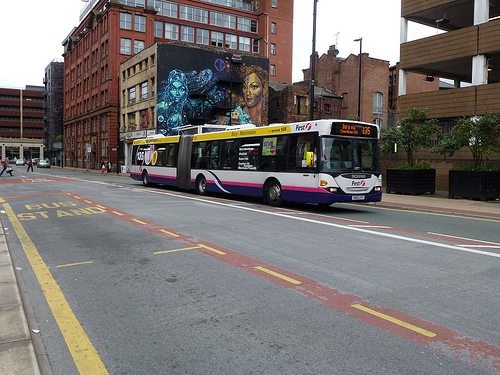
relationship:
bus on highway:
[129, 118, 382, 208] [1, 161, 499, 374]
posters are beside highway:
[156, 41, 269, 133] [1, 161, 499, 374]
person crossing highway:
[26, 157, 34, 172] [1, 161, 499, 374]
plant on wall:
[381, 108, 443, 170] [380, 155, 499, 199]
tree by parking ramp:
[430, 112, 499, 171] [398, 0, 499, 159]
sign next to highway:
[84, 144, 92, 152] [1, 161, 499, 374]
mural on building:
[156, 41, 269, 133] [120, 40, 268, 174]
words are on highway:
[16, 200, 106, 221] [1, 161, 499, 374]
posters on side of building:
[156, 41, 269, 133] [120, 40, 268, 174]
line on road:
[14, 167, 499, 258] [1, 161, 499, 374]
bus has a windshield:
[129, 118, 382, 208] [320, 135, 381, 171]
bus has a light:
[129, 118, 382, 208] [329, 187, 337, 193]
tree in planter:
[430, 112, 499, 171] [448, 169, 499, 202]